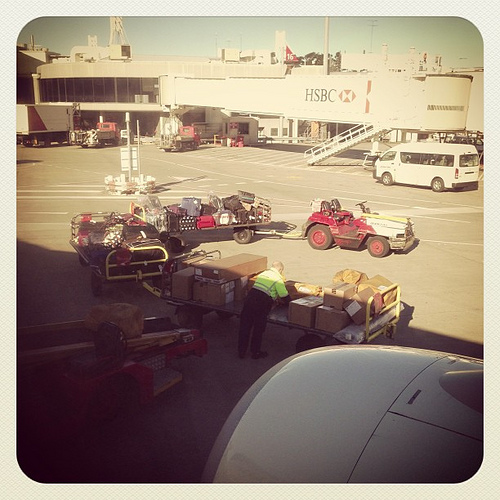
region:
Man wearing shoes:
[234, 345, 279, 361]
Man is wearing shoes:
[237, 345, 277, 362]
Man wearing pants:
[235, 305, 266, 355]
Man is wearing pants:
[234, 303, 262, 350]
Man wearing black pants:
[236, 299, 267, 355]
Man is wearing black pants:
[234, 306, 265, 353]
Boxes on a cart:
[172, 250, 401, 342]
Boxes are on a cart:
[163, 248, 398, 325]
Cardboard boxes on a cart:
[171, 251, 406, 336]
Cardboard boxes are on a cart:
[172, 254, 394, 331]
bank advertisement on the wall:
[306, 88, 356, 103]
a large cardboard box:
[191, 250, 267, 279]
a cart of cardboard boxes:
[164, 248, 401, 336]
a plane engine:
[204, 341, 483, 485]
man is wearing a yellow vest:
[237, 260, 285, 357]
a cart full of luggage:
[74, 212, 167, 283]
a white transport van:
[375, 143, 477, 190]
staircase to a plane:
[304, 112, 419, 164]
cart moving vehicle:
[303, 198, 413, 255]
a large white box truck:
[14, 102, 75, 143]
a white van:
[367, 140, 480, 194]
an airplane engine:
[197, 339, 485, 484]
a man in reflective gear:
[233, 260, 290, 360]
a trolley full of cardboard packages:
[161, 249, 406, 354]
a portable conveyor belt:
[12, 302, 214, 437]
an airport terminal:
[18, 45, 484, 165]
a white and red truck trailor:
[15, 100, 82, 150]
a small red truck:
[152, 122, 202, 154]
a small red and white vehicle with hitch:
[275, 194, 417, 260]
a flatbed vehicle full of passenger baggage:
[130, 185, 275, 252]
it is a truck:
[297, 193, 417, 258]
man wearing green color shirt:
[246, 270, 290, 300]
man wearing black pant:
[232, 292, 273, 357]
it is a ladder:
[302, 122, 381, 161]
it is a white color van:
[371, 139, 482, 192]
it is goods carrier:
[74, 210, 170, 277]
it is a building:
[44, 53, 197, 123]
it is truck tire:
[307, 222, 337, 250]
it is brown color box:
[314, 281, 367, 321]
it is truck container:
[19, 102, 78, 147]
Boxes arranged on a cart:
[199, 268, 231, 301]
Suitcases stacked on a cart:
[186, 206, 250, 221]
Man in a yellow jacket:
[263, 273, 273, 281]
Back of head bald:
[273, 261, 276, 264]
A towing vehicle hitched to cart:
[311, 218, 401, 235]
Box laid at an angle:
[353, 298, 361, 319]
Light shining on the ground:
[428, 274, 473, 317]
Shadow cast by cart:
[276, 222, 285, 229]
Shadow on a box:
[176, 276, 185, 296]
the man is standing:
[239, 261, 288, 358]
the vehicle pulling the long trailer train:
[70, 190, 418, 346]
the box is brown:
[195, 253, 268, 282]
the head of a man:
[265, 251, 288, 278]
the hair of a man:
[273, 261, 280, 269]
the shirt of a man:
[247, 264, 286, 299]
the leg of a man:
[248, 289, 283, 357]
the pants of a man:
[230, 288, 276, 352]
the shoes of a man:
[235, 339, 275, 370]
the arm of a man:
[270, 272, 293, 302]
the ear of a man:
[276, 266, 283, 274]